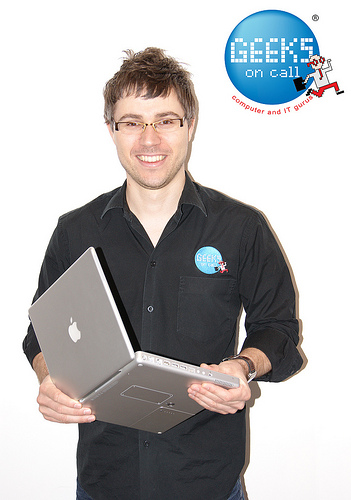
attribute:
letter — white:
[230, 37, 247, 61]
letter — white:
[243, 68, 253, 80]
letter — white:
[263, 34, 279, 65]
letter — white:
[279, 70, 287, 78]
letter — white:
[269, 69, 278, 79]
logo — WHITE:
[66, 315, 81, 342]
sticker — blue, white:
[188, 238, 236, 284]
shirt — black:
[13, 182, 310, 498]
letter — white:
[246, 34, 263, 68]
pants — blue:
[232, 480, 249, 497]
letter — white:
[195, 253, 206, 261]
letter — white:
[196, 252, 203, 264]